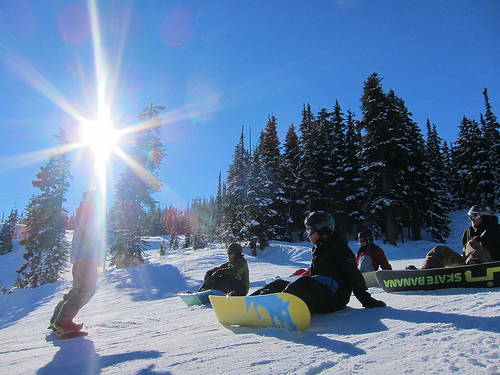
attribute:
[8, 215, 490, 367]
snow — white, covered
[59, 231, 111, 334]
man — standing, sitting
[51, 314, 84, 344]
snowboard — yellow, blue, white, black, green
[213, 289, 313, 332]
snowboard — yellow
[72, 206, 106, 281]
jacket — red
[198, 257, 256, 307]
man — sitting